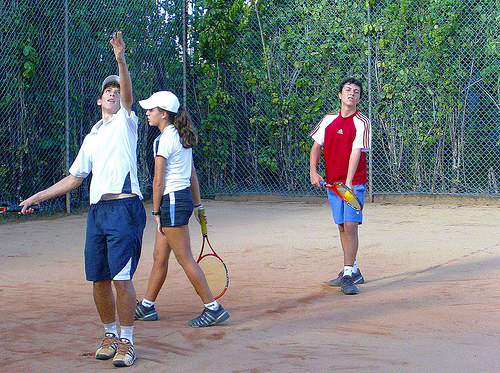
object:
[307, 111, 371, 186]
shirt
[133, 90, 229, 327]
girl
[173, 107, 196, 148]
ponytail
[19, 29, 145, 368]
boy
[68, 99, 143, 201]
shirt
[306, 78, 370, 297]
boy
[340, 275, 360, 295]
shoes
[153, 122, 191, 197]
shirt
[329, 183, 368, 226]
shorts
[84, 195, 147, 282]
shorts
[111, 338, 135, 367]
shoes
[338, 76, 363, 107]
head